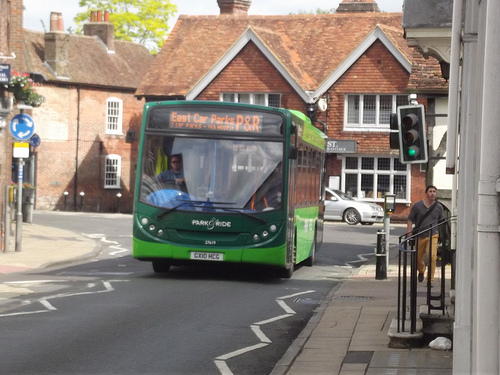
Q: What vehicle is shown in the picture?
A: A green bus.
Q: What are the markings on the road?
A: White markings for the bus to follow.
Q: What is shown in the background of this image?
A: A house with a wooden roof.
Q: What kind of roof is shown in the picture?
A: A wooden shingle roof.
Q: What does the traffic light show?
A: Green for go.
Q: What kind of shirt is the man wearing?
A: A grey t-shirt.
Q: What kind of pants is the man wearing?
A: Brown pants.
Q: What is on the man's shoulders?
A: A backpack.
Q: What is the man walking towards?
A: A metal railing.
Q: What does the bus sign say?
A: It says East Car Parks P&R.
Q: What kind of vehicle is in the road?
A: A bus.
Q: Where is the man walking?
A: On the sidewalk.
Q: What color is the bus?
A: Green.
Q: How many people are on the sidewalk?
A: One.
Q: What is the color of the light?
A: Green.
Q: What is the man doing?
A: Walking.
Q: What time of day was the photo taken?
A: Day time.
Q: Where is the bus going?
A: East Car Parks.